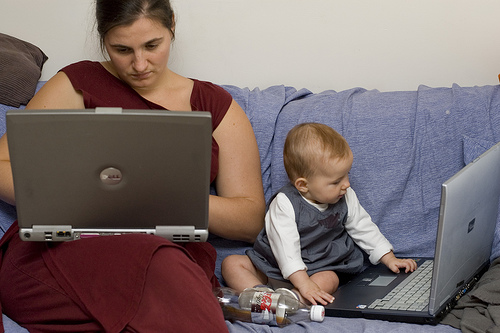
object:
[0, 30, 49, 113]
pillow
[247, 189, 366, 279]
dress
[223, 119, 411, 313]
baby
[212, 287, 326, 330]
bottle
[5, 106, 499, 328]
computer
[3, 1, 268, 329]
lady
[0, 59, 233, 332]
dress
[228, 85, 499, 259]
blanket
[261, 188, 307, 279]
sleeve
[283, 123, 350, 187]
hair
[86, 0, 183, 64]
hair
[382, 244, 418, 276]
hand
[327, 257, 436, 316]
keyboard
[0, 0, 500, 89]
wall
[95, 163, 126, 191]
logo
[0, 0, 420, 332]
family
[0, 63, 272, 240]
arm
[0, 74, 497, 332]
couch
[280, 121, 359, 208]
head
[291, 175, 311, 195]
ear